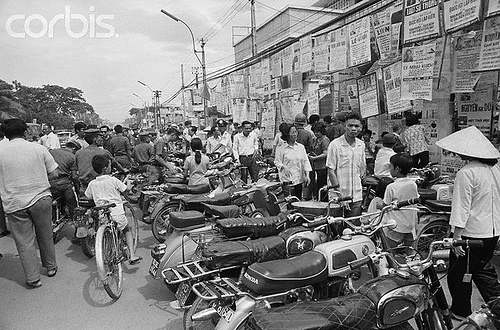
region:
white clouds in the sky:
[123, 34, 179, 51]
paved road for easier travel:
[50, 285, 91, 326]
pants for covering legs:
[8, 210, 57, 267]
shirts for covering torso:
[2, 139, 53, 201]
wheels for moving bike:
[92, 229, 127, 292]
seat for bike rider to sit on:
[96, 201, 115, 216]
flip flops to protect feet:
[133, 258, 140, 266]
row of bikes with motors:
[167, 185, 417, 315]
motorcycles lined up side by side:
[178, 183, 420, 318]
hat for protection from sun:
[437, 123, 499, 165]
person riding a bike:
[77, 146, 145, 305]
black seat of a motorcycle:
[238, 247, 330, 297]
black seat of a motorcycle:
[197, 233, 292, 272]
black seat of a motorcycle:
[215, 211, 292, 238]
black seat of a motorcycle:
[197, 198, 247, 219]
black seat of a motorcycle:
[166, 202, 211, 234]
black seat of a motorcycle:
[177, 188, 233, 208]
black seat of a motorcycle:
[240, 284, 377, 329]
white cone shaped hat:
[429, 124, 499, 163]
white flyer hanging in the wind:
[396, 37, 440, 107]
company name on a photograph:
[13, 6, 133, 61]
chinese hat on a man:
[438, 109, 496, 166]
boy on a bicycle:
[78, 149, 148, 311]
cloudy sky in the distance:
[63, 29, 181, 90]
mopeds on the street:
[166, 173, 454, 323]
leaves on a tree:
[3, 71, 98, 117]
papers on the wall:
[309, 15, 379, 75]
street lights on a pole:
[161, 6, 202, 66]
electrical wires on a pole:
[192, 6, 249, 41]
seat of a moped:
[256, 251, 321, 286]